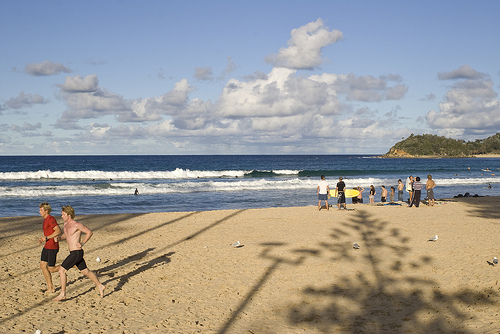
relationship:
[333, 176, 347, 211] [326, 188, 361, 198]
man holds surfboard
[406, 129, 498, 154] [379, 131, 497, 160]
trees on mountain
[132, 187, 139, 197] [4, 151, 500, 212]
man in water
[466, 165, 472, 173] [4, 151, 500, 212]
person in water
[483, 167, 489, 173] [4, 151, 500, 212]
person in water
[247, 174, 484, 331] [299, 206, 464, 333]
trees has shadow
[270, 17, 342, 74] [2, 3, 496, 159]
clouds in sky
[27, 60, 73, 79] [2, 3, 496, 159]
cloud in sky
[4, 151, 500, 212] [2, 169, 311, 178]
water has waves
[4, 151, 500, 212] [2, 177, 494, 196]
water has waves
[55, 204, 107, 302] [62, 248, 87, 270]
man wears shorts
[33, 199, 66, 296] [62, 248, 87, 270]
man wears shorts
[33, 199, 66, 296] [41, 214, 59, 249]
man wears shirt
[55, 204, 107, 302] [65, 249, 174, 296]
man has shadow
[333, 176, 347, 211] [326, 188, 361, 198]
man carries surfboard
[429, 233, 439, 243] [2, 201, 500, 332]
seagull on sand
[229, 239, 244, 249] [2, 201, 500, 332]
seagull on sand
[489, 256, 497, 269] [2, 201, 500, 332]
seagull on sand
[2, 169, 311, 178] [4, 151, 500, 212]
waves in water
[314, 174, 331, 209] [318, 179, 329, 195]
person wears shirt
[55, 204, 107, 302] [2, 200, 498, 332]
man on beach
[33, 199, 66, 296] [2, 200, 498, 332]
man on beach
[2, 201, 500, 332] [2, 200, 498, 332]
sand on beach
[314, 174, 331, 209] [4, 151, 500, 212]
person faces water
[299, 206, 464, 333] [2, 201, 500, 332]
shadow in sand